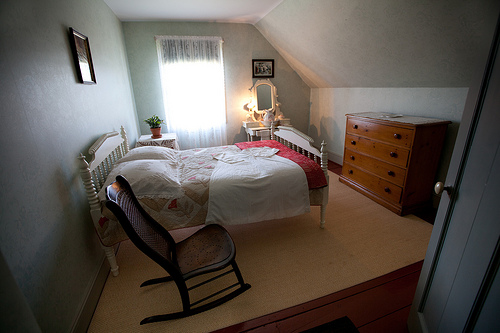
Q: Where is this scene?
A: Bedroom.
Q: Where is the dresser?
A: Right.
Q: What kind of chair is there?
A: Rocking chair.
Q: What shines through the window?
A: Sun.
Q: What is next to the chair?
A: A bed.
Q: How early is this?
A: Pretty early.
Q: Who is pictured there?
A: No person.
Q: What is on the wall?
A: Picture.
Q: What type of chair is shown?
A: Rocking chair.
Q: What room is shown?
A: Bedroom.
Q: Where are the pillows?
A: Bed.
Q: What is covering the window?
A: Curtains.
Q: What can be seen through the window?
A: Light.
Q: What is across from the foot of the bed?
A: Dresser.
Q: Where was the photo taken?
A: In a bedroom.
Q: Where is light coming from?
A: A window.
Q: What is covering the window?
A: Curtains.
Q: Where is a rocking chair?
A: Next to the bed.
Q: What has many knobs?
A: Drawers.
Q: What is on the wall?
A: Picture.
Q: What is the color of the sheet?
A: White.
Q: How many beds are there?
A: 1.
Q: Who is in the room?
A: No one.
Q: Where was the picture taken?
A: In a bedroom.